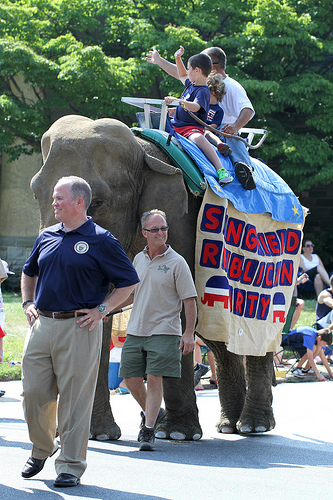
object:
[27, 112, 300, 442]
elephant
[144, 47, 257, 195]
person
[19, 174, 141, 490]
man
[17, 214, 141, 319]
polo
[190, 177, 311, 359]
sign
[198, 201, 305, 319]
republican party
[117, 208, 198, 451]
man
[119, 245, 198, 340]
polo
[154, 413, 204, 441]
foot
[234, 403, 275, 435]
foot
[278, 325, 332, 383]
boy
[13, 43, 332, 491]
parade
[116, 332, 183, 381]
shorts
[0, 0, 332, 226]
trees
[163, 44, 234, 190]
boy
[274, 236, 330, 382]
crowd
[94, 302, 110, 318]
wrist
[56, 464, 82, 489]
shoes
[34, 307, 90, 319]
belt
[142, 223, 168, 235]
sunglasses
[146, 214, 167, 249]
face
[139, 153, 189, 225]
ear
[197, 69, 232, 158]
kid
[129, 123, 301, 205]
back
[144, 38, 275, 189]
family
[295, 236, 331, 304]
woman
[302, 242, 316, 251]
sunglasses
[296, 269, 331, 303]
chair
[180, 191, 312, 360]
banner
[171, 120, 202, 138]
shorts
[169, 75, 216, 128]
tee shirt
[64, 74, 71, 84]
leaves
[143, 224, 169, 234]
glasses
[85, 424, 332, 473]
shadow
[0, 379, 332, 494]
pavement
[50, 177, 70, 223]
face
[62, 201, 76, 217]
splotches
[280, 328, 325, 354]
tee shirt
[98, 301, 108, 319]
wristwatch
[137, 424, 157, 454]
sneaker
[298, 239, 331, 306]
person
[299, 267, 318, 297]
shorts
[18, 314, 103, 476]
pants